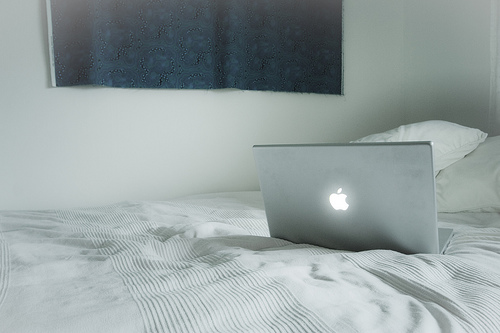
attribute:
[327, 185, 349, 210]
logo — glowing , apple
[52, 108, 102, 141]
paint — white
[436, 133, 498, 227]
pillow — white, fluffy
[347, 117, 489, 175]
pillow — fluffy, white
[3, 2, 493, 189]
walls — white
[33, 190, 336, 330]
blanket — wrinkled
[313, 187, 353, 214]
logo — mac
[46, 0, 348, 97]
panel — grey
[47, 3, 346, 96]
curtain — blue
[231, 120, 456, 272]
laptop — open